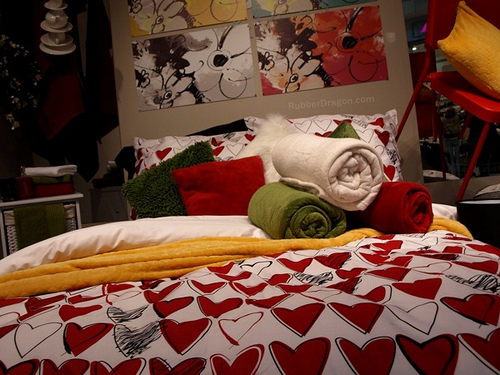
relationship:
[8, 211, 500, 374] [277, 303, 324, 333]
blanket with heart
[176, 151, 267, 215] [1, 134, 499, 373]
pillow on top of bed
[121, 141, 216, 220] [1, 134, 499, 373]
pillow on top of bed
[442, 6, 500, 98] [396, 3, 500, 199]
pillow on top of chair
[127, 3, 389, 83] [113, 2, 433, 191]
picture on wall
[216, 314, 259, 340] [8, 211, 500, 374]
heart on blanket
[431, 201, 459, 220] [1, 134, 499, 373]
sheet on top of bed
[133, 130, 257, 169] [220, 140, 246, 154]
pillow has heart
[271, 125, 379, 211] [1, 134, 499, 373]
blanket on top of bed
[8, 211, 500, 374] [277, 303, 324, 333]
blanket has heart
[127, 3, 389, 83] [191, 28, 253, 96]
picture has flower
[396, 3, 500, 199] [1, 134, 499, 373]
chair next to bed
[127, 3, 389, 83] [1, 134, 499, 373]
picture hanging above bed